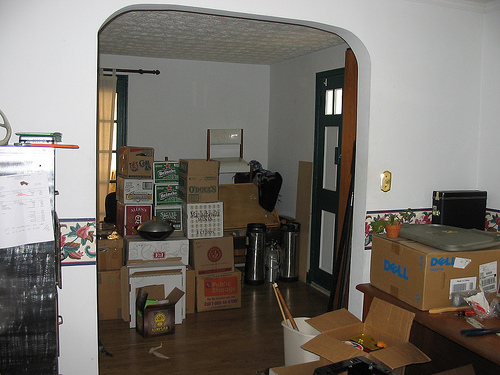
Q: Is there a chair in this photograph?
A: Yes, there is a chair.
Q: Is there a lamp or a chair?
A: Yes, there is a chair.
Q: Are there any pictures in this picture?
A: No, there are no pictures.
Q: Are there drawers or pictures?
A: No, there are no pictures or drawers.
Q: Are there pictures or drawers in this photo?
A: No, there are no pictures or drawers.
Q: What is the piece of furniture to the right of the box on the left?
A: The piece of furniture is a chair.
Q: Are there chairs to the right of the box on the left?
A: Yes, there is a chair to the right of the box.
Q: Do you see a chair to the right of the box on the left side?
A: Yes, there is a chair to the right of the box.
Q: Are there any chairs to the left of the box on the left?
A: No, the chair is to the right of the box.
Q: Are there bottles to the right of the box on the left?
A: No, there is a chair to the right of the box.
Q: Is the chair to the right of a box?
A: Yes, the chair is to the right of a box.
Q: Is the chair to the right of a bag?
A: No, the chair is to the right of a box.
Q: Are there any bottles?
A: No, there are no bottles.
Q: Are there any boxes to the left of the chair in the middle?
A: Yes, there is a box to the left of the chair.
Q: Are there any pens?
A: No, there are no pens.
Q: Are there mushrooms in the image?
A: No, there are no mushrooms.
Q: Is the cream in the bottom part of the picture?
A: Yes, the cream is in the bottom of the image.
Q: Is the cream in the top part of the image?
A: No, the cream is in the bottom of the image.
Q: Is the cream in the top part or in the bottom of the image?
A: The cream is in the bottom of the image.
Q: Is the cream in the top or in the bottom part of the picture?
A: The cream is in the bottom of the image.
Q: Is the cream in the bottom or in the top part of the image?
A: The cream is in the bottom of the image.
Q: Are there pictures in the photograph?
A: No, there are no pictures.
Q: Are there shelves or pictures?
A: No, there are no pictures or shelves.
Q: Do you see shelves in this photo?
A: No, there are no shelves.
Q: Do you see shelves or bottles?
A: No, there are no shelves or bottles.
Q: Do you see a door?
A: Yes, there is a door.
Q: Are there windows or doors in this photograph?
A: Yes, there is a door.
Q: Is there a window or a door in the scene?
A: Yes, there is a door.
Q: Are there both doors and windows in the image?
A: Yes, there are both a door and a window.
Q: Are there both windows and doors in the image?
A: Yes, there are both a door and a window.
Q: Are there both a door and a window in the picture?
A: Yes, there are both a door and a window.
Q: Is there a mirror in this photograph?
A: No, there are no mirrors.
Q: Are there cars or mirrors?
A: No, there are no mirrors or cars.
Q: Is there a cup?
A: No, there are no cups.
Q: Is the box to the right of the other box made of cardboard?
A: Yes, the box is made of cardboard.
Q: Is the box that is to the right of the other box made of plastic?
A: No, the box is made of cardboard.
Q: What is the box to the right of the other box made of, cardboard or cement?
A: The box is made of cardboard.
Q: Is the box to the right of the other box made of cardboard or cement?
A: The box is made of cardboard.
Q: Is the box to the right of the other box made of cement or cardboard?
A: The box is made of cardboard.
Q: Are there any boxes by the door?
A: Yes, there is a box by the door.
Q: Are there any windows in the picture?
A: Yes, there is a window.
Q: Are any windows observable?
A: Yes, there is a window.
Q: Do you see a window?
A: Yes, there is a window.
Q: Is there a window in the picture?
A: Yes, there is a window.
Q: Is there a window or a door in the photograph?
A: Yes, there is a window.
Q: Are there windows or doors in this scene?
A: Yes, there is a window.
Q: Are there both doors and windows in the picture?
A: Yes, there are both a window and a door.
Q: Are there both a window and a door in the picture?
A: Yes, there are both a window and a door.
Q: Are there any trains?
A: No, there are no trains.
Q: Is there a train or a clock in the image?
A: No, there are no trains or clocks.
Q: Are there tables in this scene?
A: Yes, there is a table.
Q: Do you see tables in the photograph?
A: Yes, there is a table.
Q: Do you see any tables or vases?
A: Yes, there is a table.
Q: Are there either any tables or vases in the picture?
A: Yes, there is a table.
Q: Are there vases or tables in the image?
A: Yes, there is a table.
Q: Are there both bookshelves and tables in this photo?
A: No, there is a table but no bookshelves.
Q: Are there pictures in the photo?
A: No, there are no pictures.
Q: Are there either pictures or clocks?
A: No, there are no pictures or clocks.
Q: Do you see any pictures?
A: No, there are no pictures.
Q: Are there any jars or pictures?
A: No, there are no pictures or jars.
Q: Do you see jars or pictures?
A: No, there are no pictures or jars.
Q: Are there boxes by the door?
A: Yes, there is a box by the door.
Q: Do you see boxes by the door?
A: Yes, there is a box by the door.